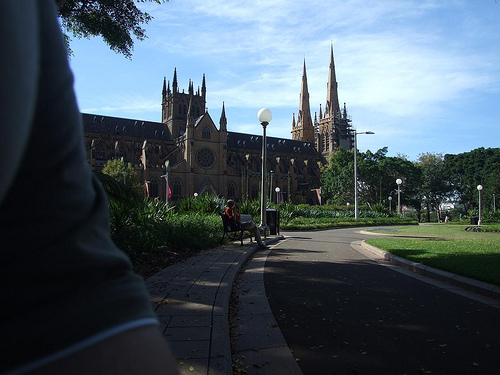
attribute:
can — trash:
[266, 211, 278, 233]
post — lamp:
[255, 120, 274, 233]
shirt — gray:
[3, 2, 183, 372]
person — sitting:
[218, 197, 268, 249]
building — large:
[76, 40, 419, 201]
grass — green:
[398, 218, 484, 285]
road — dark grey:
[276, 221, 484, 371]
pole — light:
[252, 122, 278, 235]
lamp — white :
[246, 100, 277, 122]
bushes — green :
[4, 120, 261, 338]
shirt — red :
[204, 191, 261, 230]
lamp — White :
[242, 89, 302, 264]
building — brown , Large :
[98, 71, 443, 289]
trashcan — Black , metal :
[258, 196, 303, 279]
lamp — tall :
[230, 88, 298, 238]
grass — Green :
[358, 195, 454, 286]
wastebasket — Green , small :
[256, 191, 282, 259]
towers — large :
[283, 32, 375, 276]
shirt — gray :
[5, 25, 175, 362]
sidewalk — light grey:
[135, 228, 285, 372]